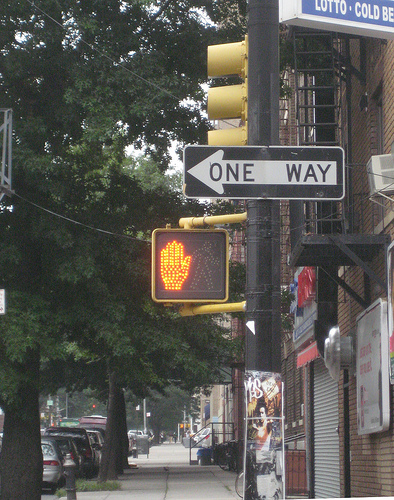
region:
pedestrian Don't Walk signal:
[148, 223, 233, 305]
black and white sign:
[176, 139, 347, 204]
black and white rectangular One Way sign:
[172, 136, 349, 209]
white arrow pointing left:
[187, 148, 341, 196]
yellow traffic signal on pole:
[202, 33, 254, 151]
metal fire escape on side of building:
[279, 21, 385, 297]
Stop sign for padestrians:
[147, 224, 234, 305]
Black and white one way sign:
[174, 142, 355, 205]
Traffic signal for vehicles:
[197, 30, 251, 147]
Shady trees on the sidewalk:
[4, 23, 249, 497]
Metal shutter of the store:
[294, 338, 346, 493]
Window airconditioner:
[360, 149, 389, 204]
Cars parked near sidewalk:
[31, 410, 157, 485]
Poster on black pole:
[238, 358, 297, 498]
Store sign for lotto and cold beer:
[276, 0, 391, 34]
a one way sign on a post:
[182, 145, 344, 199]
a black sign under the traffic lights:
[183, 145, 343, 198]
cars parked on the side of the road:
[42, 414, 114, 492]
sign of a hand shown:
[159, 240, 187, 288]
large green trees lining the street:
[0, 1, 252, 499]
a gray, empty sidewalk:
[83, 438, 241, 497]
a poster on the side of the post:
[242, 368, 284, 498]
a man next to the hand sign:
[188, 240, 217, 290]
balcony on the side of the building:
[287, 64, 386, 297]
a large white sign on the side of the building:
[353, 299, 391, 434]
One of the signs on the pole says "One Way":
[163, 134, 383, 215]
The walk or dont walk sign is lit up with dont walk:
[145, 221, 246, 321]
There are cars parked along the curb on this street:
[8, 399, 142, 498]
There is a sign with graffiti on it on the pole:
[225, 353, 331, 497]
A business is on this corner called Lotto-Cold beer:
[264, 2, 388, 59]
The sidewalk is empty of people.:
[101, 379, 215, 497]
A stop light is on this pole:
[193, 39, 312, 363]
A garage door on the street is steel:
[279, 274, 361, 497]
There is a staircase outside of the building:
[271, 26, 392, 300]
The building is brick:
[331, 61, 392, 274]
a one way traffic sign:
[183, 144, 346, 200]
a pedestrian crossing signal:
[151, 226, 228, 305]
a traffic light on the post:
[205, 33, 250, 145]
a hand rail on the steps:
[188, 420, 234, 463]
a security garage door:
[304, 357, 344, 498]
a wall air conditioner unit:
[365, 153, 393, 207]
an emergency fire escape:
[294, 26, 350, 147]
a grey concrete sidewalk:
[126, 437, 242, 498]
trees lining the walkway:
[0, 1, 149, 499]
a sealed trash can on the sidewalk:
[133, 433, 150, 461]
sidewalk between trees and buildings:
[7, 311, 373, 497]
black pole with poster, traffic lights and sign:
[147, 0, 347, 497]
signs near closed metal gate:
[284, 266, 389, 493]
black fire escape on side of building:
[286, 26, 386, 309]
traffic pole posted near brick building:
[150, 1, 345, 496]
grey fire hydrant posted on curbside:
[62, 452, 80, 498]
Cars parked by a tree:
[34, 413, 122, 474]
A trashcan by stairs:
[183, 436, 220, 469]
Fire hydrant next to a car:
[54, 438, 100, 495]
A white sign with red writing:
[346, 327, 383, 448]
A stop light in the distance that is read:
[81, 393, 103, 422]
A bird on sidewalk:
[155, 458, 203, 490]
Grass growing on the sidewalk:
[70, 473, 122, 491]